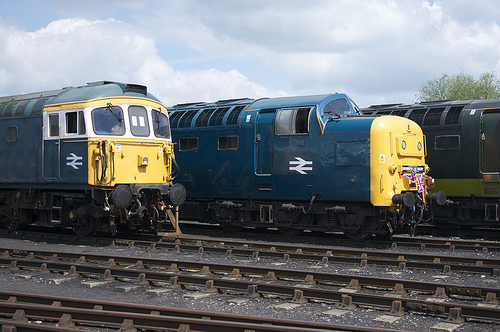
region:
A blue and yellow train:
[1, 75, 186, 232]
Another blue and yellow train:
[166, 88, 429, 233]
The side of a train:
[431, 102, 498, 226]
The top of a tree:
[404, 70, 499, 100]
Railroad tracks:
[1, 248, 496, 330]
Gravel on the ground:
[199, 296, 222, 310]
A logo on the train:
[62, 148, 87, 173]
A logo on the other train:
[287, 150, 315, 178]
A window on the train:
[273, 105, 313, 135]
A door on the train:
[251, 107, 276, 177]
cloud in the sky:
[51, 18, 156, 60]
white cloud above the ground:
[59, 15, 161, 74]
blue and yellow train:
[323, 89, 433, 199]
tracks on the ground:
[366, 230, 487, 330]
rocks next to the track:
[325, 258, 364, 275]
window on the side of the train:
[260, 90, 322, 150]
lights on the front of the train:
[393, 128, 433, 156]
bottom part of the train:
[215, 199, 365, 234]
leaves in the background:
[421, 73, 493, 97]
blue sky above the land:
[17, 3, 49, 24]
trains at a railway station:
[1, 74, 494, 321]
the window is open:
[55, 108, 87, 134]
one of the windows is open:
[279, 104, 316, 141]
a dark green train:
[433, 113, 498, 200]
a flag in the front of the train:
[398, 154, 446, 188]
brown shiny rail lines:
[286, 244, 346, 291]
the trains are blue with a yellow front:
[8, 52, 410, 271]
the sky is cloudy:
[258, 5, 369, 45]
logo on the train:
[276, 146, 312, 193]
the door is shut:
[253, 110, 274, 175]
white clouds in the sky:
[299, 18, 379, 65]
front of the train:
[39, 73, 194, 283]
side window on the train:
[261, 100, 325, 150]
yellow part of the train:
[352, 105, 448, 221]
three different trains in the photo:
[26, 79, 495, 295]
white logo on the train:
[279, 150, 316, 188]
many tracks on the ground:
[195, 244, 392, 330]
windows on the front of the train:
[93, 101, 172, 143]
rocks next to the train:
[196, 290, 229, 320]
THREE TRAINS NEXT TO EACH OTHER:
[0, 70, 499, 247]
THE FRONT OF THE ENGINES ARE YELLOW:
[85, 95, 440, 212]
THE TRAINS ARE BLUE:
[0, 81, 438, 235]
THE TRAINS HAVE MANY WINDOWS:
[0, 89, 471, 141]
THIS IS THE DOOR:
[472, 100, 499, 180]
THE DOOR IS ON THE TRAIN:
[247, 98, 286, 190]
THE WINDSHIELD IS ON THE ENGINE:
[78, 95, 173, 150]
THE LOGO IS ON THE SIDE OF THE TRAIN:
[48, 143, 92, 171]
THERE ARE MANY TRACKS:
[1, 212, 498, 330]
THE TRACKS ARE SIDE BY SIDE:
[0, 205, 499, 330]